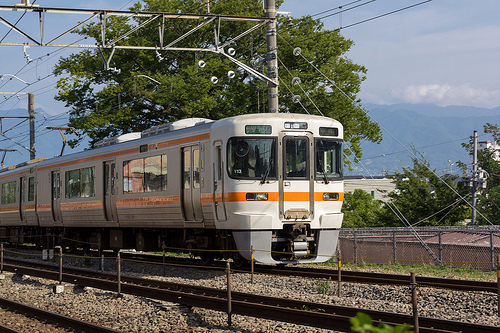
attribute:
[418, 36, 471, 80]
sky — blue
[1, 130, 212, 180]
stripes — orange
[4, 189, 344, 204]
stripes — orange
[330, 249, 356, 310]
post — metal 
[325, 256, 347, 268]
stripe — yellow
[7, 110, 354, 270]
train — white, going